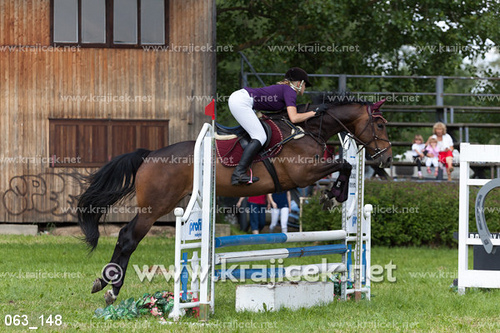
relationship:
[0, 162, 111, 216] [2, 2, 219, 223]
graffiti on building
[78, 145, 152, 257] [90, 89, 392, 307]
tail on horse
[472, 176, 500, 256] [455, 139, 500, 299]
horseshoe on fence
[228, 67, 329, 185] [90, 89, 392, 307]
girl riding horse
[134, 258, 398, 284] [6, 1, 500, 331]
logo across picture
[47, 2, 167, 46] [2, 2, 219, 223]
window on building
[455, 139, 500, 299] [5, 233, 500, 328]
fence in grass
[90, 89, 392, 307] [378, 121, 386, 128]
horse has eye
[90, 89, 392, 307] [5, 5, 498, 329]
horse at competition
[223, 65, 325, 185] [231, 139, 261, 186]
girl has boot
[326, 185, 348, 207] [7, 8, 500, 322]
hooves in air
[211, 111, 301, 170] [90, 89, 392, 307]
saddle on horse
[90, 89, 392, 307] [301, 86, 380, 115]
horse has mane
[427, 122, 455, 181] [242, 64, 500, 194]
person in stands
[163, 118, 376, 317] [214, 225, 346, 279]
jump has rails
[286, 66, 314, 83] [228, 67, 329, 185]
helmet on girl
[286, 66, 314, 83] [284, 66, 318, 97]
helmet on head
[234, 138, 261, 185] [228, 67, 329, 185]
boot on girl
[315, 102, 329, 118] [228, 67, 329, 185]
glove on girl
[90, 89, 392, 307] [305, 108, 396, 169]
horse has rein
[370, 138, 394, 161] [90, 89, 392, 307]
bridge piece on horse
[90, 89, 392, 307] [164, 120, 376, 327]
horse jumping obstacle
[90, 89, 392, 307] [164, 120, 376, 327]
horse over obstacle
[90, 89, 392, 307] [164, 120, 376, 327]
horse jumping over obstacle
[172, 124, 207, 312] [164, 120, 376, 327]
flap on obstacle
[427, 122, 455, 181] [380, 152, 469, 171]
person on bench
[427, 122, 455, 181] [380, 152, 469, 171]
person sitting on bench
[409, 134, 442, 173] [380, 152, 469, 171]
kids sitting on bench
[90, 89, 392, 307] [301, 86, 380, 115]
horse with mane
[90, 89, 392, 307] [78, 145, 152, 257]
horse with tail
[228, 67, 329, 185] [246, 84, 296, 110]
girl has shirt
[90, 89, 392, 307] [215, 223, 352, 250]
horse jumping rail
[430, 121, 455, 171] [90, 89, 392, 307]
person watching horse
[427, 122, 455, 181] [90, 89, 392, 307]
person watching horse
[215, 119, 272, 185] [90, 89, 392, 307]
saddle on horse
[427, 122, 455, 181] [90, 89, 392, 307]
person riding horse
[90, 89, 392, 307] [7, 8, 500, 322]
horse will jump in air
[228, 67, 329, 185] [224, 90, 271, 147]
girl wearing pants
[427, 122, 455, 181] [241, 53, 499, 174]
person sitting in bleachers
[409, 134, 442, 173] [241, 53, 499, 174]
kids sitting in bleachers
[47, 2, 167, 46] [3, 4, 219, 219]
window on house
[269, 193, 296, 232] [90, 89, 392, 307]
person walking toward horse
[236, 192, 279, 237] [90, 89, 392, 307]
person walking toward horse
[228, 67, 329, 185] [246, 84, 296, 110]
girl wearing shirt